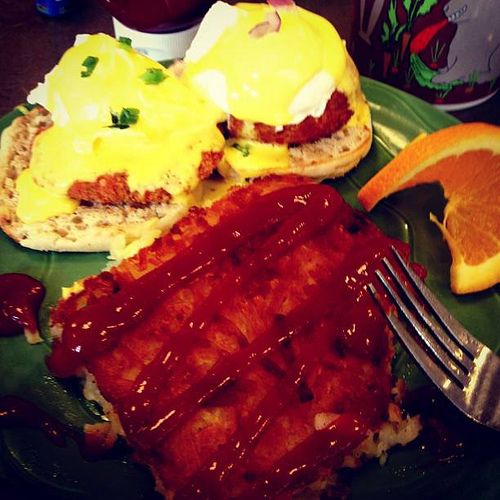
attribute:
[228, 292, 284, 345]
bbq sauce — red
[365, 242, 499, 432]
fork — silver, metal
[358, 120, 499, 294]
orange — sliced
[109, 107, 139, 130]
onion — green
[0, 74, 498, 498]
plate — green, porcelain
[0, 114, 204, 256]
biscuit — white, english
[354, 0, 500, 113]
mug — painted, purple, plastic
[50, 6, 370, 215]
sauce — yellow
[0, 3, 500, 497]
food — delicious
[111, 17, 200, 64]
lid — white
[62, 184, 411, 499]
hash browns — brown